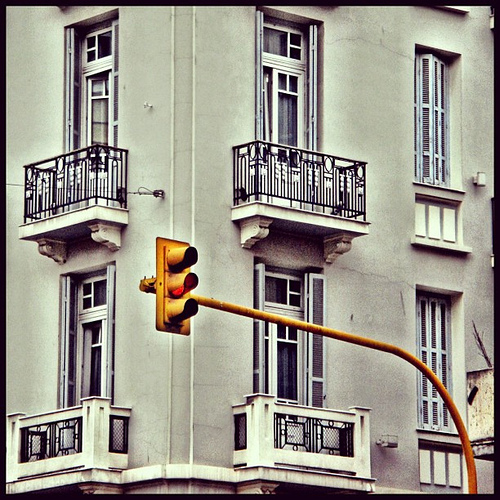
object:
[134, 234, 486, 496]
traffic light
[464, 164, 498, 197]
light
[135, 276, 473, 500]
pole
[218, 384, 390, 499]
balcony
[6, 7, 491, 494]
building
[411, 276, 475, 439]
window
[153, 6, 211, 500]
building corner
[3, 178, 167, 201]
wire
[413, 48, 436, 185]
shutter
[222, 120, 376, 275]
balcony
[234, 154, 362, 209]
railing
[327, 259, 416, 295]
crack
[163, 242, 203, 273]
top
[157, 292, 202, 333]
bottom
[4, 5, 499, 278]
second floor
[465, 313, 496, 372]
tree branch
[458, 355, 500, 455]
patio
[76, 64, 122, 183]
patio door